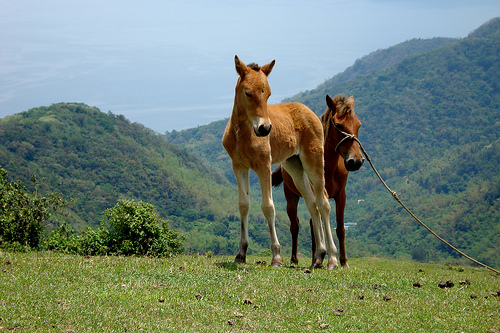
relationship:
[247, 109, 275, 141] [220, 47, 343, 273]
snout of horse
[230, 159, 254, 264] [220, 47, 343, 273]
leg belonging to horse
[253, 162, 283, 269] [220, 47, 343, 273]
leg belonging to horse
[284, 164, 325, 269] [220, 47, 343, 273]
leg belonging to horse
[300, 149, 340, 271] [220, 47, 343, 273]
leg belonging to horse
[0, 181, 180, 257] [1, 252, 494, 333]
bushes on field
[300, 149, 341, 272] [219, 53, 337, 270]
leg on colt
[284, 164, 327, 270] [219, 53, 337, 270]
leg on colt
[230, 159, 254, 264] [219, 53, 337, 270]
leg on colt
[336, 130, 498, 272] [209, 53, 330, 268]
rope on horse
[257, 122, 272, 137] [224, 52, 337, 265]
nose of horse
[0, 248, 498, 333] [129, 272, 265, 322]
grass in field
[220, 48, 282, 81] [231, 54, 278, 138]
ears on top of head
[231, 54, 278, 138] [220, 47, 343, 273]
head of horse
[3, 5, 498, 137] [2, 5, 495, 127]
sky with clouds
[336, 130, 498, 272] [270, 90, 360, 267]
rope on horse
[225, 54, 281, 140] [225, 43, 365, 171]
head of horses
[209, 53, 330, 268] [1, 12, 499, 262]
horse standing on hilltop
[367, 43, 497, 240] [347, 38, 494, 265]
hill covered in trees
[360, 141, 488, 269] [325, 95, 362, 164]
rope tied to head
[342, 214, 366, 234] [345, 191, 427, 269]
building in valley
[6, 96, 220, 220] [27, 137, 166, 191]
mountain side covered with trees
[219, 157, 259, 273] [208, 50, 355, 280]
leg of pony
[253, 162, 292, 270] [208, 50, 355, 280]
leg of pony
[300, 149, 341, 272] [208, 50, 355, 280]
leg of pony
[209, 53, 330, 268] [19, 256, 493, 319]
horse standing in grass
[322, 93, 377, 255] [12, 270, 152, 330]
horse on grass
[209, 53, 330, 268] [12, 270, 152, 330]
horse on grass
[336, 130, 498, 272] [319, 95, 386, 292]
rope tied to horse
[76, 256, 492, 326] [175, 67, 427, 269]
grass growing under horses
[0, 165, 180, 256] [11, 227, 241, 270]
bushes on cliffside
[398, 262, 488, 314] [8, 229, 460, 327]
dirt in grass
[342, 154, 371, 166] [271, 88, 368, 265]
nose of horse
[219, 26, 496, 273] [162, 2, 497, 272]
forest covering mountain